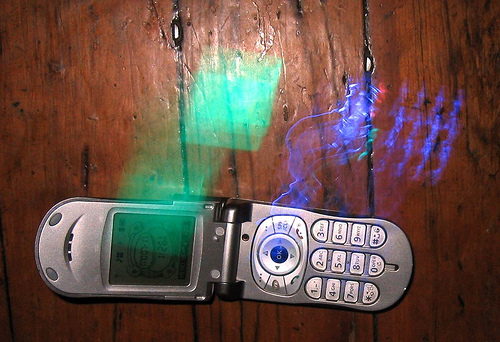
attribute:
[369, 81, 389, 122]
blur — red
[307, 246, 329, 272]
button — small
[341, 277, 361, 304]
button — small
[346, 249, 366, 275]
button — small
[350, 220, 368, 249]
button — small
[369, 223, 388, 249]
button — small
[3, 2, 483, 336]
table — wooden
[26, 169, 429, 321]
phone — grey 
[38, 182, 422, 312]
cell phone — light grey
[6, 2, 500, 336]
wood table — wooden, brown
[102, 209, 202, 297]
phone screen — green, black, small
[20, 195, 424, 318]
old phone — silver, flip style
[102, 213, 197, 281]
green screen — blurry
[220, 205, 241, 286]
phone hinge — silver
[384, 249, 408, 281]
phone speaker — small